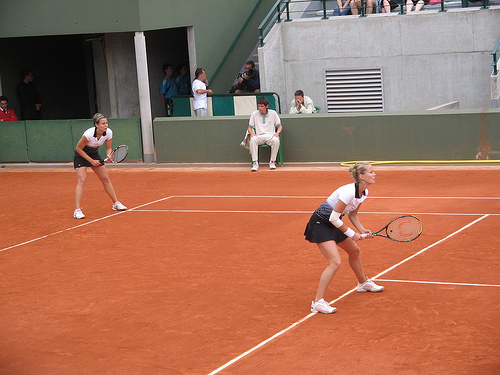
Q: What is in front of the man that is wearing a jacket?
A: The wall is in front of the man.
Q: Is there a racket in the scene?
A: Yes, there is a racket.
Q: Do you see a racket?
A: Yes, there is a racket.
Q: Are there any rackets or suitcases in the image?
A: Yes, there is a racket.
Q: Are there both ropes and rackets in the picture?
A: No, there is a racket but no ropes.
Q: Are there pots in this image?
A: No, there are no pots.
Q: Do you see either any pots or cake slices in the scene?
A: No, there are no pots or cake slices.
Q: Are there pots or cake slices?
A: No, there are no pots or cake slices.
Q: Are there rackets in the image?
A: Yes, there is a racket.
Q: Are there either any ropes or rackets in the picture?
A: Yes, there is a racket.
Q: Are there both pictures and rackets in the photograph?
A: No, there is a racket but no pictures.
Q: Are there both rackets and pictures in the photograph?
A: No, there is a racket but no pictures.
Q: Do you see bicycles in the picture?
A: No, there are no bicycles.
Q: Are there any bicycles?
A: No, there are no bicycles.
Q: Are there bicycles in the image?
A: No, there are no bicycles.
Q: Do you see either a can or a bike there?
A: No, there are no bikes or cans.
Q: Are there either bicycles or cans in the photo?
A: No, there are no bicycles or cans.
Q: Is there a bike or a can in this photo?
A: No, there are no bikes or cans.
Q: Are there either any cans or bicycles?
A: No, there are no bicycles or cans.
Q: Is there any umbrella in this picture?
A: No, there are no umbrellas.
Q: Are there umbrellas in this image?
A: No, there are no umbrellas.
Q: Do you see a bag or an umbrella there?
A: No, there are no umbrellas or bags.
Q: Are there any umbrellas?
A: No, there are no umbrellas.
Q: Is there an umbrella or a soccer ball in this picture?
A: No, there are no umbrellas or soccer balls.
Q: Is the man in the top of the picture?
A: Yes, the man is in the top of the image.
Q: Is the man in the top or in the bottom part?
A: The man is in the top of the image.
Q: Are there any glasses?
A: No, there are no glasses.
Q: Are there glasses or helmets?
A: No, there are no glasses or helmets.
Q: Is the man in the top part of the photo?
A: Yes, the man is in the top of the image.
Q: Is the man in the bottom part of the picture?
A: No, the man is in the top of the image.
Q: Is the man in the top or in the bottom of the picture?
A: The man is in the top of the image.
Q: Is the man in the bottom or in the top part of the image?
A: The man is in the top of the image.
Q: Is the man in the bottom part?
A: No, the man is in the top of the image.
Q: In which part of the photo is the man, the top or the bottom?
A: The man is in the top of the image.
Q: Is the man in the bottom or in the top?
A: The man is in the top of the image.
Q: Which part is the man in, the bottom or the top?
A: The man is in the top of the image.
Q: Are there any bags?
A: No, there are no bags.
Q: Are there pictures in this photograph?
A: No, there are no pictures.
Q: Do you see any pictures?
A: No, there are no pictures.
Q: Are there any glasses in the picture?
A: No, there are no glasses.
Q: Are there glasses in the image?
A: No, there are no glasses.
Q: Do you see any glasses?
A: No, there are no glasses.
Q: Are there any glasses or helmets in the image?
A: No, there are no glasses or helmets.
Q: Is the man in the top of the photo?
A: Yes, the man is in the top of the image.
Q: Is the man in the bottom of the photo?
A: No, the man is in the top of the image.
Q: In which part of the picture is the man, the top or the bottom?
A: The man is in the top of the image.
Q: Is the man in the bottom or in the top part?
A: The man is in the top of the image.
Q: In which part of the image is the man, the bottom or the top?
A: The man is in the top of the image.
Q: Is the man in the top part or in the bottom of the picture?
A: The man is in the top of the image.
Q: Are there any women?
A: Yes, there is a woman.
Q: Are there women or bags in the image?
A: Yes, there is a woman.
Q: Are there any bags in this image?
A: No, there are no bags.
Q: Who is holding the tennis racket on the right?
A: The woman is holding the tennis racket.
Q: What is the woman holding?
A: The woman is holding the racket.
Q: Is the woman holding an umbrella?
A: No, the woman is holding a racket.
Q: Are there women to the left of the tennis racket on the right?
A: Yes, there is a woman to the left of the racket.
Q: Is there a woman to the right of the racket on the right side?
A: No, the woman is to the left of the tennis racket.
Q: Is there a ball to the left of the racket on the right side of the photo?
A: No, there is a woman to the left of the tennis racket.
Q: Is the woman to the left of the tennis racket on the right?
A: Yes, the woman is to the left of the racket.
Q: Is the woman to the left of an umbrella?
A: No, the woman is to the left of the racket.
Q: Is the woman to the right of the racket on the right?
A: No, the woman is to the left of the tennis racket.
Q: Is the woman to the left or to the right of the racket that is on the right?
A: The woman is to the left of the racket.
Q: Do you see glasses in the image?
A: No, there are no glasses.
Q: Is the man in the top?
A: Yes, the man is in the top of the image.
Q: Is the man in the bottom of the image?
A: No, the man is in the top of the image.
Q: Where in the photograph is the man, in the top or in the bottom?
A: The man is in the top of the image.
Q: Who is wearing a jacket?
A: The man is wearing a jacket.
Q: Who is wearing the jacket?
A: The man is wearing a jacket.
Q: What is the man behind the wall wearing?
A: The man is wearing a jacket.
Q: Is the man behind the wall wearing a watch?
A: No, the man is wearing a jacket.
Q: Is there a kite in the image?
A: No, there are no kites.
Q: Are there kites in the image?
A: No, there are no kites.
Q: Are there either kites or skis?
A: No, there are no kites or skis.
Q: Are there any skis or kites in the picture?
A: No, there are no kites or skis.